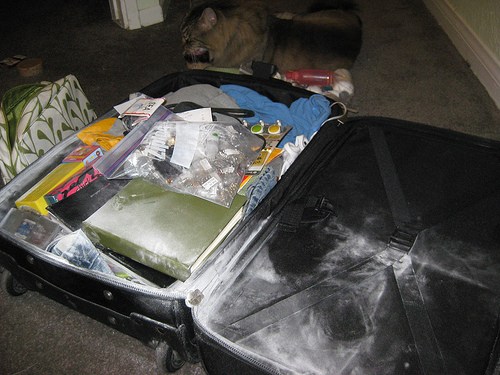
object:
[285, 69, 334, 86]
item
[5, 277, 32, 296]
bus tire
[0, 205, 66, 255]
item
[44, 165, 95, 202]
item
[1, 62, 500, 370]
suitcase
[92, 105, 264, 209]
item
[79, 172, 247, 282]
item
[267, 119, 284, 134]
item